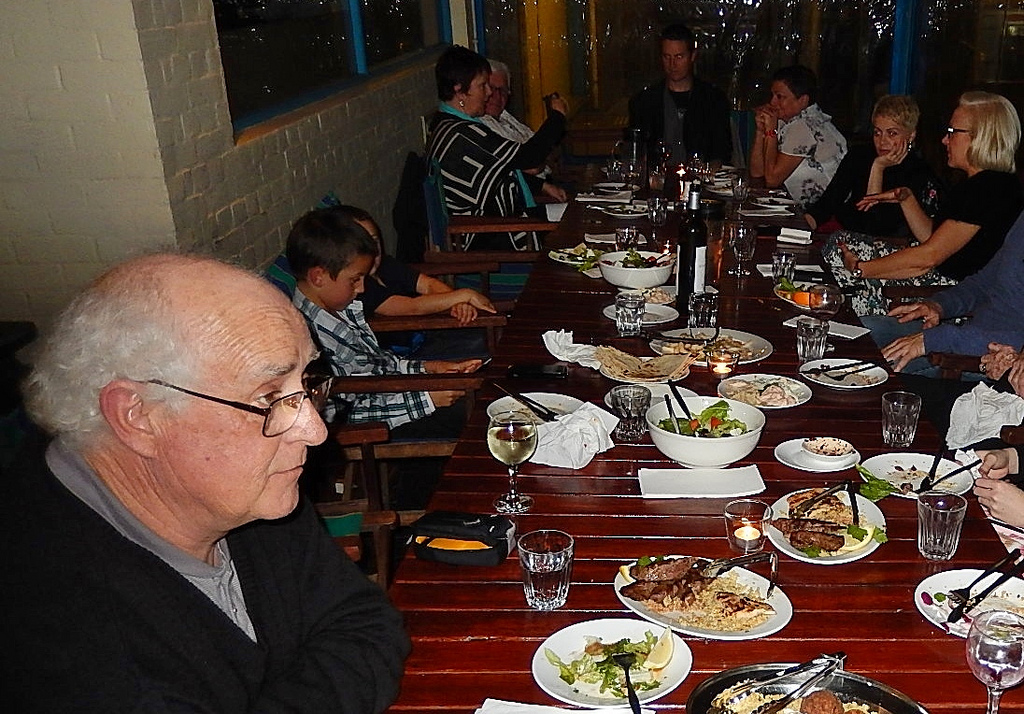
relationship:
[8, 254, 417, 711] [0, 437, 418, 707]
man wearing jacket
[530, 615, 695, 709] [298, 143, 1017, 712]
plate on table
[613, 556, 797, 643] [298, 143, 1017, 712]
plate on table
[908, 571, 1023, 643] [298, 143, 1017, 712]
plate on table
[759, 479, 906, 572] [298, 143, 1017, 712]
plate on table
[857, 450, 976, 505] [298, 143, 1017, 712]
plate on table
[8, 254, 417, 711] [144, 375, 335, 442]
man wearing eyeglasses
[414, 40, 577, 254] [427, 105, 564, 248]
woman wearing shirt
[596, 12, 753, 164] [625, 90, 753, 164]
man wearing coat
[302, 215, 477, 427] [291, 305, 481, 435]
boy wearing shirt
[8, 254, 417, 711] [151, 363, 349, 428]
man wearing glasses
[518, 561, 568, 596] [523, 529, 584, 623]
water in glass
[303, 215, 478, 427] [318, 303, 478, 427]
boy wearing shirt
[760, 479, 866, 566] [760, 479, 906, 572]
food on plate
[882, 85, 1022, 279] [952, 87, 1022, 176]
lady has hair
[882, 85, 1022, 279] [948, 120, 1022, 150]
lady wearing glasses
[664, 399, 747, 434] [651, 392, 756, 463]
salad in bowl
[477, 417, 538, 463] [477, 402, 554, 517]
wine in glass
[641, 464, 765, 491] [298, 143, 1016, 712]
napkin on table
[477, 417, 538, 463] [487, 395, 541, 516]
wine in goblet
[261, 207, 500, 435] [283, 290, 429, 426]
boy wearing jacket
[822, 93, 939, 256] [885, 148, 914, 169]
woman sits with her chin in her hand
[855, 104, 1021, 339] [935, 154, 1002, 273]
woman wears shirt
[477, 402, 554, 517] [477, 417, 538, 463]
glass full of wine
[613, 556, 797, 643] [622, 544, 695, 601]
plate with steak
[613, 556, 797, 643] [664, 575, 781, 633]
plate with pasta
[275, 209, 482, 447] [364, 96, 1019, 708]
child sitting at table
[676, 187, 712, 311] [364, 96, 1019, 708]
bottle on dinner table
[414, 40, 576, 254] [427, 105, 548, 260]
woman wearing shirt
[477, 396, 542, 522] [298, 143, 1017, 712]
wine glass on table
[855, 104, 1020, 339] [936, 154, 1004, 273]
woman wearing shirt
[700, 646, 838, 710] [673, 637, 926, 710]
tongs on platter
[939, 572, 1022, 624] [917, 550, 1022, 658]
knife on plate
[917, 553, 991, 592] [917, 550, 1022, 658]
fork on plate